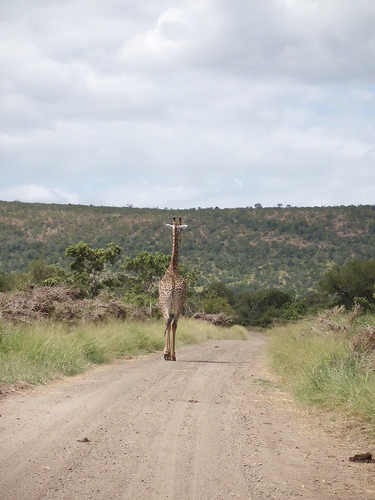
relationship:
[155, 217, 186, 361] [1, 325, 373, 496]
giraffe on road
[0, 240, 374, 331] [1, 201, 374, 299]
trees before mountain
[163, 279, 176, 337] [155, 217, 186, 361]
tail on giraffe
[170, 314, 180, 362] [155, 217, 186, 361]
leg of giraffe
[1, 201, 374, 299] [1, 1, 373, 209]
mountain under sky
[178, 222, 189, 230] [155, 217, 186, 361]
ear on giraffe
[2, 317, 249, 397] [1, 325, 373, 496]
grass next to road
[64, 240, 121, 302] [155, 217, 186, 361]
trees behind giraffe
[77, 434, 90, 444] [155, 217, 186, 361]
excrement of giraffe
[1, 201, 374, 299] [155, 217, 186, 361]
mountain behind giraffe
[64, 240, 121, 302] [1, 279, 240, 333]
trees on hill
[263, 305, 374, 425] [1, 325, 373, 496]
grass next to road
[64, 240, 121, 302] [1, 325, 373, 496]
tree next to road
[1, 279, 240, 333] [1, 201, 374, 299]
hill in front of mountain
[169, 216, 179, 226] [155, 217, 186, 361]
horn on giraffe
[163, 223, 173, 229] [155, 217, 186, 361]
ear on giraffe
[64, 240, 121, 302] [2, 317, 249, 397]
tree behind grass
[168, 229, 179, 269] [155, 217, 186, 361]
neck on giraffe